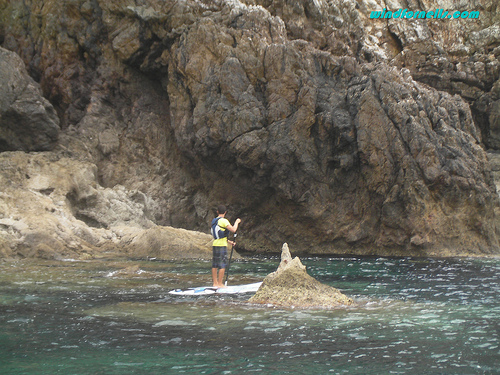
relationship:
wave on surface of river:
[356, 259, 380, 270] [4, 250, 499, 374]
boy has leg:
[209, 204, 242, 287] [219, 264, 228, 289]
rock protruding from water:
[250, 241, 354, 311] [1, 251, 499, 374]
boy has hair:
[209, 204, 242, 287] [215, 203, 232, 217]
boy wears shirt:
[209, 204, 242, 287] [212, 217, 232, 247]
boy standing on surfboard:
[209, 204, 242, 287] [166, 281, 264, 298]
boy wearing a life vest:
[209, 204, 242, 287] [210, 216, 229, 239]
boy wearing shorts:
[209, 204, 242, 287] [212, 244, 227, 270]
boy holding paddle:
[209, 204, 242, 287] [225, 211, 247, 286]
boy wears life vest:
[209, 204, 242, 287] [210, 216, 229, 239]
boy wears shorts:
[210, 202, 244, 286] [211, 244, 231, 270]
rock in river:
[250, 241, 354, 311] [4, 250, 499, 374]